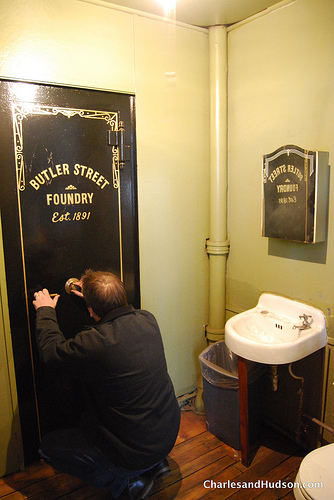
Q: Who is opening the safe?
A: A man.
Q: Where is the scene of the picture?
A: A bathroom.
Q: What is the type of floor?
A: Wood.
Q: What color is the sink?
A: White.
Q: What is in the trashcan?
A: A liner.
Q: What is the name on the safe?
A: Butler Street Foundry.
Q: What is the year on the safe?
A: 1891.